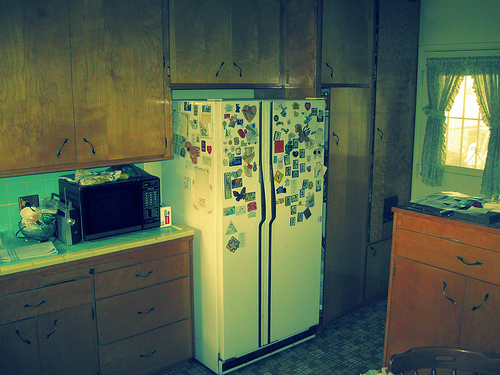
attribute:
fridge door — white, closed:
[215, 96, 327, 343]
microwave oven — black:
[76, 171, 155, 236]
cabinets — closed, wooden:
[6, 6, 178, 167]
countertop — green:
[31, 233, 187, 254]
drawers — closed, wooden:
[99, 258, 196, 359]